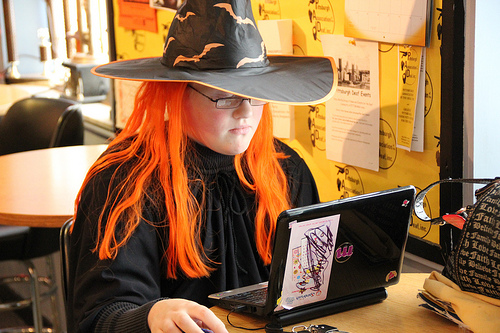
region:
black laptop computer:
[207, 182, 413, 324]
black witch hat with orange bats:
[91, 1, 340, 107]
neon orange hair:
[116, 79, 222, 297]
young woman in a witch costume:
[80, 1, 296, 283]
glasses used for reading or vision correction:
[179, 77, 277, 117]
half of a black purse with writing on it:
[409, 159, 497, 330]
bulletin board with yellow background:
[96, 2, 467, 267]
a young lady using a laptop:
[71, 1, 414, 327]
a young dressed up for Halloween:
[66, 2, 294, 331]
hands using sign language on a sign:
[395, 48, 424, 89]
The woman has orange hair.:
[71, 76, 294, 281]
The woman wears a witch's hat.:
[87, 0, 355, 122]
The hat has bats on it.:
[156, 1, 274, 77]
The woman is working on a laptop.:
[179, 172, 444, 330]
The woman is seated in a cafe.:
[0, 14, 458, 331]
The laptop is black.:
[200, 180, 427, 332]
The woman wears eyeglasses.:
[184, 82, 276, 117]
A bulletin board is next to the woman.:
[252, 1, 447, 205]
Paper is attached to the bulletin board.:
[303, 27, 403, 182]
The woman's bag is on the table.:
[408, 166, 498, 307]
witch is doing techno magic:
[36, 4, 406, 328]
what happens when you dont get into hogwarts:
[79, 11, 424, 323]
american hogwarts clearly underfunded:
[57, 17, 355, 324]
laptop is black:
[211, 180, 436, 312]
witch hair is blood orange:
[78, 40, 311, 265]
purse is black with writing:
[411, 147, 498, 314]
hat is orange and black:
[96, 23, 333, 151]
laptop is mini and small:
[237, 161, 425, 325]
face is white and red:
[154, 55, 290, 185]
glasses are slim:
[102, 21, 279, 166]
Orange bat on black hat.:
[172, 42, 227, 68]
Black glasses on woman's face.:
[190, 82, 277, 109]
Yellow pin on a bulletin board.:
[347, 40, 357, 46]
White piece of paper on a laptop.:
[279, 215, 344, 307]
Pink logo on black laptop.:
[332, 240, 355, 260]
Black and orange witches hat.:
[92, 2, 344, 102]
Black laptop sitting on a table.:
[207, 186, 416, 318]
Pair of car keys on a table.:
[294, 324, 339, 331]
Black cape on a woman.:
[67, 130, 324, 331]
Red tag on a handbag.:
[441, 213, 466, 230]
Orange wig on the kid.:
[58, 45, 353, 282]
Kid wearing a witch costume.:
[56, 0, 370, 330]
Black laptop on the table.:
[196, 164, 421, 327]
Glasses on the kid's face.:
[177, 78, 316, 135]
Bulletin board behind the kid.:
[91, 0, 467, 243]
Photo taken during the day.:
[0, 2, 152, 161]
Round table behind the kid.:
[1, 131, 196, 253]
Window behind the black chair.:
[10, 0, 146, 145]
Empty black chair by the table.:
[0, 42, 87, 274]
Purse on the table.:
[409, 148, 499, 315]